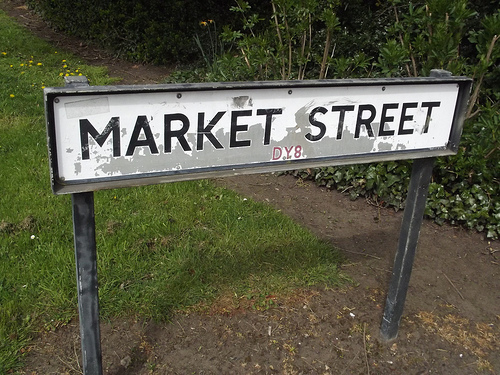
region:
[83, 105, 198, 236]
the sign is white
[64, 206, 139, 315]
this is a bar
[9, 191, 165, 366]
the bar is black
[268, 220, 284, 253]
this is a patch of grass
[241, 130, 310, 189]
this says the letters DY8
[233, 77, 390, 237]
the paint is chipping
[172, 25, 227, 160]
this is a metal bolt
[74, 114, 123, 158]
black letter on sign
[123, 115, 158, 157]
black letter on sign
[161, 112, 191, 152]
black letter on sign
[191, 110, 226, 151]
black letter on sign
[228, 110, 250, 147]
black letter on sign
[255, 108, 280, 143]
black letter on sign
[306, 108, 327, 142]
black letter on sign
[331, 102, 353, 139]
black letter on sign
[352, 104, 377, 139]
black letter on sign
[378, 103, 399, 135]
black letter on sign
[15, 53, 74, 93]
yellow flowers in the grass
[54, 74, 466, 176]
a white sign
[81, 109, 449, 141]
writing on the sign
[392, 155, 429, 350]
the black pole of the sign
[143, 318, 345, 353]
dirt on the ground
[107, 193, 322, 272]
grass next to the dirt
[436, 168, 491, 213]
leaves on the ground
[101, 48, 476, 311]
a dirt pathway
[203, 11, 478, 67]
trees behind the sign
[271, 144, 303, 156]
red letters on the sign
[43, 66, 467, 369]
Sign posted on the ground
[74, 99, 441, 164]
Writing on the sign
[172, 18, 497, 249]
Patch of flowers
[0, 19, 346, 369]
Area of grass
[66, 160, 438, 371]
Couple of poles connecting the sign to the ground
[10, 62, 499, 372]
Walkway for people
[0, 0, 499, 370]
Area away from wildlife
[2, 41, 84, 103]
Several yellow flowers in the grass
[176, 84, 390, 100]
Bolts on the sign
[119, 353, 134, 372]
Rock on the ground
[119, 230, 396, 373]
the shadow of the sign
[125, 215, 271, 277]
some grass on the ground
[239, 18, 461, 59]
many tree branches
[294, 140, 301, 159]
the number 8 in red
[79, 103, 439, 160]
it says MARKET STREET in black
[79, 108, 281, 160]
the word MARKET in capital letter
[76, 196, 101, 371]
a metal vertical bar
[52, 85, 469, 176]
the background of the sign is white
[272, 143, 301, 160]
it says DY8 in red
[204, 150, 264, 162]
there is not white paint on this area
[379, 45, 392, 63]
a leaf on a stem